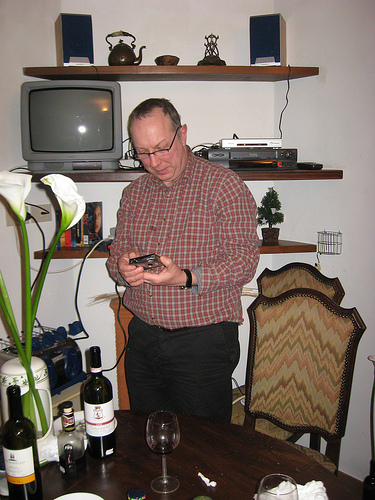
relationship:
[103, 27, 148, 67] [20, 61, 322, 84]
kettle on shelf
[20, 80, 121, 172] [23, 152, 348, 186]
tv on shelf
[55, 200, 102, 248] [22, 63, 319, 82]
books on shelf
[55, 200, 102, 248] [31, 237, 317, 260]
books on shelf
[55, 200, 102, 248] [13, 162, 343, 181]
books on shelf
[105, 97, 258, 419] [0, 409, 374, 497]
man next to table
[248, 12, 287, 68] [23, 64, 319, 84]
speaker on shelf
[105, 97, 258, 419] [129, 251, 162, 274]
man looking at camera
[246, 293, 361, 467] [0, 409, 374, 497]
dining chair next to table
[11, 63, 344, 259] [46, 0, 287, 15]
shelves in corner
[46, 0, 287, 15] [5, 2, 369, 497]
corner of room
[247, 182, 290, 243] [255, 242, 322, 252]
item on shelf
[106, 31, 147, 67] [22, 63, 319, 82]
kettle on shelf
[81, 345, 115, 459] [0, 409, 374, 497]
bottle on table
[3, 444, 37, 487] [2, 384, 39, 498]
label on bottle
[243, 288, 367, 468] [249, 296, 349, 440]
dining chair with cushion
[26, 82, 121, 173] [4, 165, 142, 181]
tv on shelf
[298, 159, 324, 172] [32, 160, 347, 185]
remote on shelf